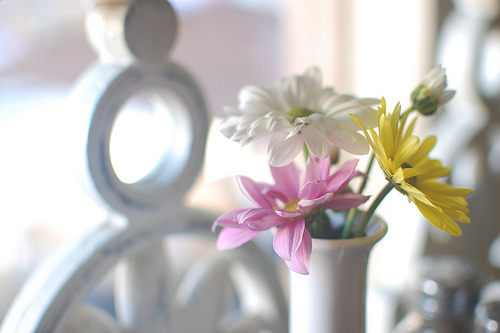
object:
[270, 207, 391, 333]
vase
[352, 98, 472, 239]
flower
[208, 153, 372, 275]
daisy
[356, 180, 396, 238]
stem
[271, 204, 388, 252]
rim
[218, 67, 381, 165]
bud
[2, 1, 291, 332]
decoration